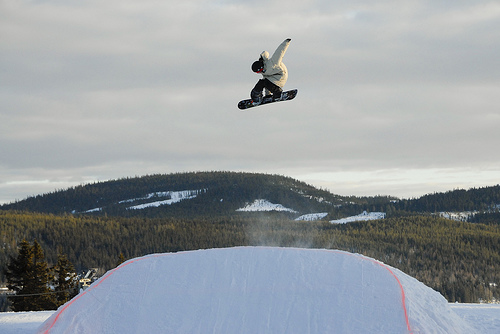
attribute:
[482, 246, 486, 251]
leaf — green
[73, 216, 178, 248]
leaf — green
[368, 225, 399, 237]
leaf — green